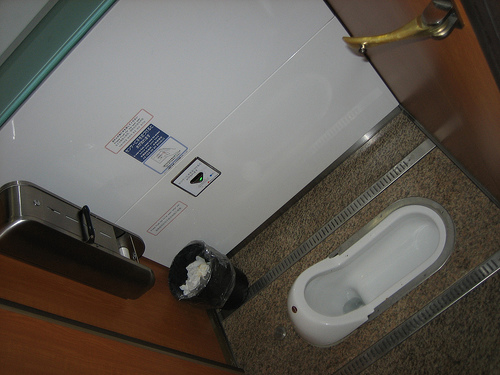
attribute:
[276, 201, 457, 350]
toilet — white, porcelain, built in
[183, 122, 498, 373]
floor — speckled, brown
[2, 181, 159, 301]
toilet paper holder — silver, wall mounted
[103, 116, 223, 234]
signs — instructional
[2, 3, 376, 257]
wall — brick, white, tiled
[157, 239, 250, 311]
trash can — small, black, lined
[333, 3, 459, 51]
wall mount hook — gold colored, gold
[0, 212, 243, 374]
wall — brown, wooden, dark brown, dark wood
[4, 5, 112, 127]
beam — blue, green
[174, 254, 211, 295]
garbage — white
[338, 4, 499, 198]
door — wooden, brown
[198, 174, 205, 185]
light — green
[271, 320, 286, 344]
flush button — chrome, small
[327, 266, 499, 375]
track — steel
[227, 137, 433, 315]
track — steel